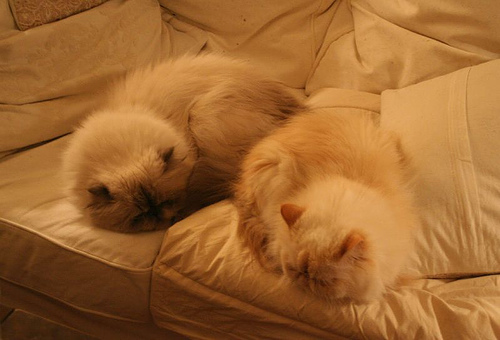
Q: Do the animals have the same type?
A: Yes, all the animals are cats.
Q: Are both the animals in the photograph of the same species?
A: Yes, all the animals are cats.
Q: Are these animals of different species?
A: No, all the animals are cats.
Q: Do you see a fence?
A: No, there are no fences.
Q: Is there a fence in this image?
A: No, there are no fences.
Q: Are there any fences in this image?
A: No, there are no fences.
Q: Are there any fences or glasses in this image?
A: No, there are no fences or glasses.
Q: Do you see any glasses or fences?
A: No, there are no fences or glasses.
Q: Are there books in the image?
A: No, there are no books.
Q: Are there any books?
A: No, there are no books.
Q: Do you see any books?
A: No, there are no books.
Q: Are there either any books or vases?
A: No, there are no books or vases.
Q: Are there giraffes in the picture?
A: No, there are no giraffes.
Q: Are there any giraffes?
A: No, there are no giraffes.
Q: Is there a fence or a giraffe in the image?
A: No, there are no giraffes or fences.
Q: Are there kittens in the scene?
A: Yes, there is a kitten.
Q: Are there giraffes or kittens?
A: Yes, there is a kitten.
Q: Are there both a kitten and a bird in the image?
A: No, there is a kitten but no birds.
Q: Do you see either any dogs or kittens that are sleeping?
A: Yes, the kitten is sleeping.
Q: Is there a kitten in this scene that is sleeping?
A: Yes, there is a kitten that is sleeping.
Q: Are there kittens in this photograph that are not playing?
A: Yes, there is a kitten that is sleeping.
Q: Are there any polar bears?
A: No, there are no polar bears.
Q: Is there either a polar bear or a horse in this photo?
A: No, there are no polar bears or horses.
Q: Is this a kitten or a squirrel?
A: This is a kitten.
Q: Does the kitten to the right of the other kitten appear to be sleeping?
A: Yes, the kitten is sleeping.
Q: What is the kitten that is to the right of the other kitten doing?
A: The kitten is sleeping.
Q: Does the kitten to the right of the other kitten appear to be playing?
A: No, the kitten is sleeping.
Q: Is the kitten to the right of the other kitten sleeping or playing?
A: The kitten is sleeping.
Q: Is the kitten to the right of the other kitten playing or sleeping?
A: The kitten is sleeping.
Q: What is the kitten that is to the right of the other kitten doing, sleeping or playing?
A: The kitten is sleeping.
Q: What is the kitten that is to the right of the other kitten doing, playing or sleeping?
A: The kitten is sleeping.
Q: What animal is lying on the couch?
A: The animal is a kitten.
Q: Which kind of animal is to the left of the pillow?
A: The animal is a kitten.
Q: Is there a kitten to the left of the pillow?
A: Yes, there is a kitten to the left of the pillow.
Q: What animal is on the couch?
A: The animal is a kitten.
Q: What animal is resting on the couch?
A: The kitten is resting on the couch.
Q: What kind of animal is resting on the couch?
A: The animal is a kitten.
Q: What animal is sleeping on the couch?
A: The kitten is sleeping on the couch.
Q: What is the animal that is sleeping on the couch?
A: The animal is a kitten.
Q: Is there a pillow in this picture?
A: Yes, there is a pillow.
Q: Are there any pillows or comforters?
A: Yes, there is a pillow.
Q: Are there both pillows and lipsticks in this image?
A: No, there is a pillow but no lipsticks.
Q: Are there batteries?
A: No, there are no batteries.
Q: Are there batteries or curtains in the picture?
A: No, there are no batteries or curtains.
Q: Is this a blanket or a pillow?
A: This is a pillow.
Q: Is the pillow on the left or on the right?
A: The pillow is on the right of the image.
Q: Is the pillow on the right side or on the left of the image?
A: The pillow is on the right of the image.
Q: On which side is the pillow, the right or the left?
A: The pillow is on the right of the image.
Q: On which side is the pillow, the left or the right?
A: The pillow is on the right of the image.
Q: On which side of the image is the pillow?
A: The pillow is on the right of the image.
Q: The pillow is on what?
A: The pillow is on the couch.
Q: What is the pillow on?
A: The pillow is on the couch.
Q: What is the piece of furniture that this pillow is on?
A: The piece of furniture is a couch.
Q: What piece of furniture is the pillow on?
A: The pillow is on the couch.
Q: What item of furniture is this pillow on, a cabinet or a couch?
A: The pillow is on a couch.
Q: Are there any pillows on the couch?
A: Yes, there is a pillow on the couch.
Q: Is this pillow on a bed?
A: No, the pillow is on a couch.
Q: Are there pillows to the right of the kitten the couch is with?
A: Yes, there is a pillow to the right of the kitten.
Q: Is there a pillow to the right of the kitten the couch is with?
A: Yes, there is a pillow to the right of the kitten.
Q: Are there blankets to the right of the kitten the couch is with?
A: No, there is a pillow to the right of the kitten.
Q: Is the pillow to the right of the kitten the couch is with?
A: Yes, the pillow is to the right of the kitten.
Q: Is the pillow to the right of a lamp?
A: No, the pillow is to the right of the kitten.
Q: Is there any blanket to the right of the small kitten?
A: No, there is a pillow to the right of the kitten.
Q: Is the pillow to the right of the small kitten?
A: Yes, the pillow is to the right of the kitten.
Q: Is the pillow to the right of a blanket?
A: No, the pillow is to the right of the kitten.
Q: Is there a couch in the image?
A: Yes, there is a couch.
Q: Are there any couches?
A: Yes, there is a couch.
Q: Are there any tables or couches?
A: Yes, there is a couch.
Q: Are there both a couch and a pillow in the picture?
A: Yes, there are both a couch and a pillow.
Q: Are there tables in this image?
A: No, there are no tables.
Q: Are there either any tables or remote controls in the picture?
A: No, there are no tables or remote controls.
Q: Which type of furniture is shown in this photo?
A: The furniture is a couch.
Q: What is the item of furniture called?
A: The piece of furniture is a couch.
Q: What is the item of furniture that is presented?
A: The piece of furniture is a couch.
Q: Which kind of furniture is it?
A: The piece of furniture is a couch.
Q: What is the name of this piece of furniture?
A: This is a couch.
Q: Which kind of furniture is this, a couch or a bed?
A: This is a couch.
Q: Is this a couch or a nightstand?
A: This is a couch.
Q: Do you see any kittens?
A: Yes, there is a kitten.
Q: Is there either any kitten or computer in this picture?
A: Yes, there is a kitten.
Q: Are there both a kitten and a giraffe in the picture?
A: No, there is a kitten but no giraffes.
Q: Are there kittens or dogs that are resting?
A: Yes, the kitten is resting.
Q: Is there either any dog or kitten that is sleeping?
A: Yes, the kitten is sleeping.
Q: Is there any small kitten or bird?
A: Yes, there is a small kitten.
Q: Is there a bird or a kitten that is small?
A: Yes, the kitten is small.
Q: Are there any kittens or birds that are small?
A: Yes, the kitten is small.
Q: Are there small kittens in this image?
A: Yes, there is a small kitten.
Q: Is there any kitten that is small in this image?
A: Yes, there is a small kitten.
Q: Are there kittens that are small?
A: Yes, there is a kitten that is small.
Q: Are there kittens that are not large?
A: Yes, there is a small kitten.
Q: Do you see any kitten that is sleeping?
A: Yes, there is a kitten that is sleeping.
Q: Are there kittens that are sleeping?
A: Yes, there is a kitten that is sleeping.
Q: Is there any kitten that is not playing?
A: Yes, there is a kitten that is sleeping.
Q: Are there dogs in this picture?
A: No, there are no dogs.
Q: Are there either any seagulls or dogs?
A: No, there are no dogs or seagulls.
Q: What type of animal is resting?
A: The animal is a kitten.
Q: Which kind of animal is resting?
A: The animal is a kitten.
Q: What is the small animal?
A: The animal is a kitten.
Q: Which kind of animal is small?
A: The animal is a kitten.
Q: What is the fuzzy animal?
A: The animal is a kitten.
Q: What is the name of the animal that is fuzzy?
A: The animal is a kitten.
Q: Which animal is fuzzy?
A: The animal is a kitten.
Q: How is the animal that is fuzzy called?
A: The animal is a kitten.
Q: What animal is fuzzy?
A: The animal is a kitten.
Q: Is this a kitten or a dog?
A: This is a kitten.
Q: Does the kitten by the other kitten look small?
A: Yes, the kitten is small.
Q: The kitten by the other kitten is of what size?
A: The kitten is small.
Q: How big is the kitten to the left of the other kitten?
A: The kitten is small.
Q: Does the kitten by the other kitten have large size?
A: No, the kitten is small.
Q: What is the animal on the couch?
A: The animal is a kitten.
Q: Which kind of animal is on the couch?
A: The animal is a kitten.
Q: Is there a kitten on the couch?
A: Yes, there is a kitten on the couch.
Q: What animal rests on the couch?
A: The kitten rests on the couch.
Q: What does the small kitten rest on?
A: The kitten rests on the couch.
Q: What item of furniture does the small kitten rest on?
A: The kitten rests on the couch.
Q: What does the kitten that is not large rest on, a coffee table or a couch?
A: The kitten rests on a couch.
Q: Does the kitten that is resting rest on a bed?
A: No, the kitten rests on a couch.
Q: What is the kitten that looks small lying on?
A: The kitten is lying on the couch.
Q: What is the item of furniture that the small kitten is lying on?
A: The piece of furniture is a couch.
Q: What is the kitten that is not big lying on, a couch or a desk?
A: The kitten is lying on a couch.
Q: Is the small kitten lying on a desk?
A: No, the kitten is lying on a couch.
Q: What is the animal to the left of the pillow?
A: The animal is a kitten.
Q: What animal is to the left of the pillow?
A: The animal is a kitten.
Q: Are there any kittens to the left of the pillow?
A: Yes, there is a kitten to the left of the pillow.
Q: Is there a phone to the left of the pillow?
A: No, there is a kitten to the left of the pillow.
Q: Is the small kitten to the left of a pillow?
A: Yes, the kitten is to the left of a pillow.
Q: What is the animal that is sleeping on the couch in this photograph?
A: The animal is a kitten.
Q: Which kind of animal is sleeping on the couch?
A: The animal is a kitten.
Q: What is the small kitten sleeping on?
A: The kitten is sleeping on the couch.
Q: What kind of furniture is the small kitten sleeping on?
A: The kitten is sleeping on the couch.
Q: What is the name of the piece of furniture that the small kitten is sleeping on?
A: The piece of furniture is a couch.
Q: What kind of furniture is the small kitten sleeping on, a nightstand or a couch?
A: The kitten is sleeping on a couch.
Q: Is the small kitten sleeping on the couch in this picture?
A: Yes, the kitten is sleeping on the couch.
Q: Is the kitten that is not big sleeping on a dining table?
A: No, the kitten is sleeping on the couch.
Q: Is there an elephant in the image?
A: No, there are no elephants.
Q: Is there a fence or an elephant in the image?
A: No, there are no elephants or fences.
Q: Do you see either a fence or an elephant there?
A: No, there are no elephants or fences.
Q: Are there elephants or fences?
A: No, there are no elephants or fences.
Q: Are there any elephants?
A: No, there are no elephants.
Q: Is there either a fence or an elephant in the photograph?
A: No, there are no elephants or fences.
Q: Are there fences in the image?
A: No, there are no fences.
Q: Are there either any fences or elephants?
A: No, there are no fences or elephants.